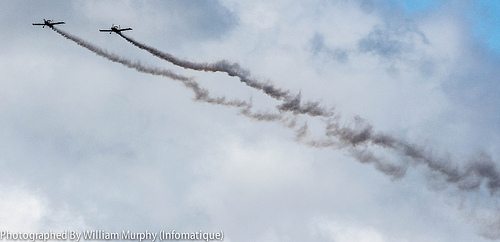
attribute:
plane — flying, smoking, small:
[99, 21, 136, 42]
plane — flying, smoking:
[31, 14, 66, 36]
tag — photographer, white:
[0, 226, 227, 241]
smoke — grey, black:
[102, 40, 270, 108]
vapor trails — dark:
[113, 48, 368, 142]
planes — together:
[31, 17, 134, 38]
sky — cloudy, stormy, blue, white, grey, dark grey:
[5, 8, 474, 238]